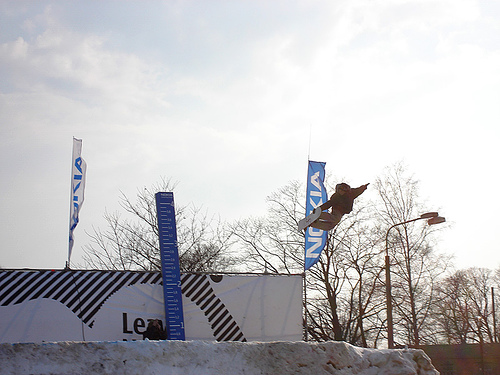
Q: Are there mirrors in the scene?
A: No, there are no mirrors.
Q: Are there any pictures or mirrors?
A: No, there are no mirrors or pictures.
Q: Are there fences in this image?
A: No, there are no fences.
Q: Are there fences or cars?
A: No, there are no fences or cars.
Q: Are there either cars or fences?
A: No, there are no fences or cars.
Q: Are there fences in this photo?
A: No, there are no fences.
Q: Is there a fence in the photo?
A: No, there are no fences.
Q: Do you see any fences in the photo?
A: No, there are no fences.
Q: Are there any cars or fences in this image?
A: No, there are no fences or cars.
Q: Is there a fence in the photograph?
A: No, there are no fences.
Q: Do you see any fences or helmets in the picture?
A: No, there are no fences or helmets.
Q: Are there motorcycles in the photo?
A: No, there are no motorcycles.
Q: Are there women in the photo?
A: No, there are no women.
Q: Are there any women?
A: No, there are no women.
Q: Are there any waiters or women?
A: No, there are no women or waiters.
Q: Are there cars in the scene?
A: No, there are no cars.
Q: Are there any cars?
A: No, there are no cars.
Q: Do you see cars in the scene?
A: No, there are no cars.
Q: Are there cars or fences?
A: No, there are no cars or fences.